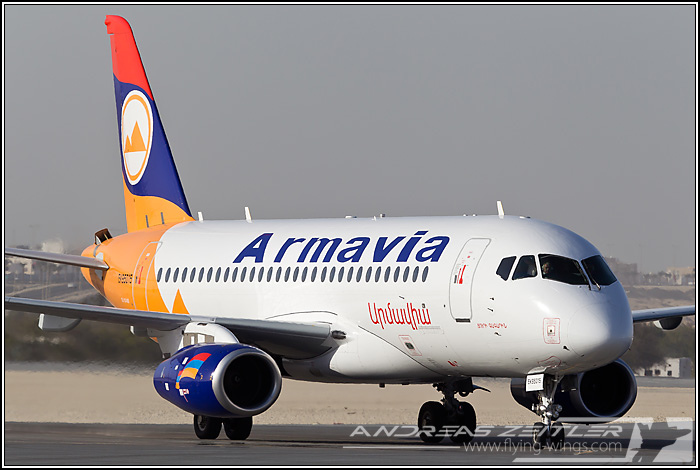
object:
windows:
[153, 260, 431, 286]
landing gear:
[528, 390, 570, 449]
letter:
[233, 230, 449, 264]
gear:
[408, 395, 486, 435]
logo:
[75, 87, 184, 191]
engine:
[143, 336, 294, 426]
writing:
[362, 292, 434, 335]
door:
[442, 234, 489, 323]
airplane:
[0, 13, 694, 440]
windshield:
[495, 252, 615, 290]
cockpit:
[485, 214, 635, 371]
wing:
[9, 287, 339, 357]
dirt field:
[8, 369, 699, 427]